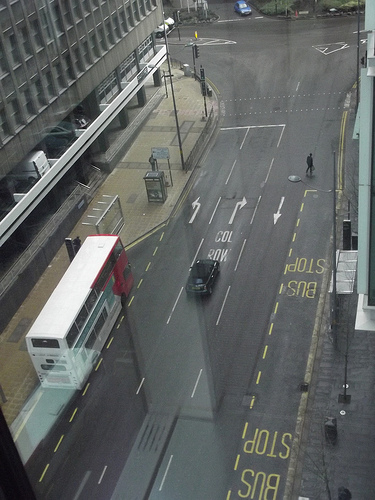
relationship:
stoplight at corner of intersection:
[191, 43, 199, 81] [169, 14, 364, 130]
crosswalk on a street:
[219, 88, 350, 122] [19, 22, 357, 498]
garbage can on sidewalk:
[325, 414, 337, 444] [280, 6, 373, 498]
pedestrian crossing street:
[307, 154, 316, 174] [182, 109, 351, 288]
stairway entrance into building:
[75, 161, 109, 196] [0, 26, 170, 144]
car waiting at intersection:
[229, 0, 253, 17] [184, 17, 357, 140]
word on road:
[243, 427, 291, 459] [256, 198, 303, 416]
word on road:
[237, 468, 280, 499] [256, 198, 303, 416]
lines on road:
[179, 153, 309, 312] [226, 142, 295, 262]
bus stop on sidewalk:
[84, 191, 124, 237] [3, 61, 216, 427]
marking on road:
[218, 122, 288, 147] [22, 17, 339, 498]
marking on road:
[259, 156, 275, 188] [22, 17, 339, 498]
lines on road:
[224, 158, 237, 186] [22, 17, 339, 498]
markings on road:
[215, 285, 232, 324] [22, 17, 339, 498]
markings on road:
[231, 237, 246, 269] [22, 17, 339, 498]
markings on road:
[247, 196, 262, 223] [22, 17, 339, 498]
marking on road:
[264, 156, 275, 184] [22, 17, 339, 498]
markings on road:
[190, 366, 202, 401] [22, 17, 339, 498]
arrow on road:
[187, 197, 202, 224] [22, 17, 339, 498]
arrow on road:
[188, 196, 202, 224] [24, 5, 364, 498]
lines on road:
[211, 177, 316, 486] [228, 152, 302, 313]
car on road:
[172, 250, 225, 307] [245, 146, 303, 287]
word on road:
[288, 282, 317, 300] [24, 5, 364, 498]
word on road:
[237, 468, 281, 500] [24, 5, 364, 498]